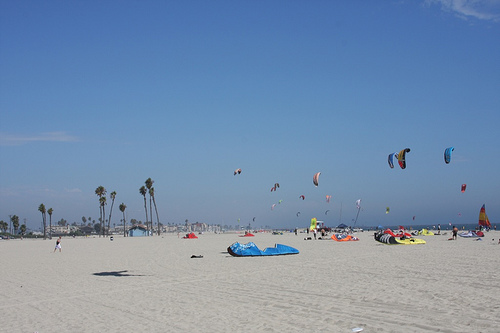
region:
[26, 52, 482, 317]
People are enjoying the beach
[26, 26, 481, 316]
The people are playing in the sand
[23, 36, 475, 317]
The people are enjoying the sunshine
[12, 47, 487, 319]
The people are enjoying their day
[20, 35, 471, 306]
The people are close to the ocean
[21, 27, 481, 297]
The people are under a blue sky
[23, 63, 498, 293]
People are enjoying swimming today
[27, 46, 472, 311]
Many nice people are at the beach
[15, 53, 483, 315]
The beach has many visitors today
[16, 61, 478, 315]
The people are playing games on the beach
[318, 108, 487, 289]
These are many flags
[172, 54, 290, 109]
This is a clear sky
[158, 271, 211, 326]
This is a sandy beach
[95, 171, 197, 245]
These are pine trees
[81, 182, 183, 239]
The palm trees are long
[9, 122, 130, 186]
This is a cloud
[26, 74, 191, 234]
The cloud is white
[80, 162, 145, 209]
The palm trees have green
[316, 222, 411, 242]
This is a crowd of people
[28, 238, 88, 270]
This is one person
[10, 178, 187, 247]
The palm trees on the beach.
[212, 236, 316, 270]
The blue structure on the sand.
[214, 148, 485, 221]
The parasails in the air.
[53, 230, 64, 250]
The person in white shorts on the left.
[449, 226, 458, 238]
The person in black shorts on the right.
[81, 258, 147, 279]
The shadow on the sand.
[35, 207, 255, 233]
The buildings in the distance.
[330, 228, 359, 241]
The orange structure in the middle on the sand.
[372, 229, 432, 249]
The black, white and yellow structure on the sand.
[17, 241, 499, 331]
The tracks on the sand.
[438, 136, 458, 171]
kite flying in the sky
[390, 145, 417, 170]
kite flying in the sky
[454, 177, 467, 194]
kite flying in the sky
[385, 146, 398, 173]
kite flying in the sky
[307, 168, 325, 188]
kite flying in the sky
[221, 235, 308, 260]
kite on the beach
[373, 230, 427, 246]
kite on the beach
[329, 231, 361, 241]
kite on the beach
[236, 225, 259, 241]
kite on the beach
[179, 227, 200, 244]
kite on the beach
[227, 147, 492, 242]
lots of kites flying in the air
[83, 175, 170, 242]
grove of palm trees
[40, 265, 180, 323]
sand on a beach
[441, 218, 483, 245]
people flying their kites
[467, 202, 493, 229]
a sailboat out on the ocean water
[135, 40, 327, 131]
a clear, blue day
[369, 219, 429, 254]
large kite on the beach before flying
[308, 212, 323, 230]
lifeguard stand can be see in the distance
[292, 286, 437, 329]
tire tracks in the sand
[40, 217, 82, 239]
a building with a view of the beach